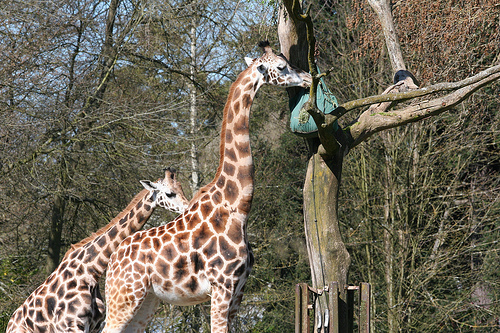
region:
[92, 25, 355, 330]
tall giraffe looking at the tree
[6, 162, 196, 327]
smaller giraffe standing behind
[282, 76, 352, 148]
blue bag in the tree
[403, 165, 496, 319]
bare branches on the tree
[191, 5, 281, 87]
blue skies behind tree branches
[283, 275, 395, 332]
wooden makeshift fence around tree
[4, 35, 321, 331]
adult giraffe and baby giraffe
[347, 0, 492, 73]
few leaves left on the tree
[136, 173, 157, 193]
white ear on giraffe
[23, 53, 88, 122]
blue skies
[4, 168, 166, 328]
Giraffe standing by trees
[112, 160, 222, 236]
Ears on a giraffe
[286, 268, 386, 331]
Wood posts around a tree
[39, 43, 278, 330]
Two giraffes by trees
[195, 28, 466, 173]
Giraffe head by a tree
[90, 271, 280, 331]
Four giraffe legs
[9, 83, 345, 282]
Trees behind giraffes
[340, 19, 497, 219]
Brown and green trees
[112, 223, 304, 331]
Orange and brown giraffe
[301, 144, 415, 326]
Green moss on a tree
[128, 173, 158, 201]
tan ears on small giraffe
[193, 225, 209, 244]
dark brown spot on large giraffe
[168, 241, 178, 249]
white spot on giraffe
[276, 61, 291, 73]
slanted eye on giraffe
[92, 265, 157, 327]
wide hind leg on giraffe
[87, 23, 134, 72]
large bare branch on tree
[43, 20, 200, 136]
lots of bare tall trees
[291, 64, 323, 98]
giraffe's mouth on tree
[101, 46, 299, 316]
large giraffe standing on ground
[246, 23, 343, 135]
A giraffe eating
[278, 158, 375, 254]
The bark of a tree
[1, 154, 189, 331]
A giraffe standing next to another giraffe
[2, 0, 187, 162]
Leafless trees behind the giraffes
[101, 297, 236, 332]
Front and back legs of the giraffe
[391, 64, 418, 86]
A black object on the tree branch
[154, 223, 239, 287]
Brown and black spots on the giraffe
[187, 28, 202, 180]
The bark of a tree in the distance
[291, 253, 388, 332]
Bottom of the tree secured in a wooden object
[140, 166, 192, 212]
A giraffes head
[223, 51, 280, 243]
the girrafe is very tall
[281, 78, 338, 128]
the sack is green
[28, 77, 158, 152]
the trees are bare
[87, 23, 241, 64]
the sky is cloudless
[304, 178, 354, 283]
the tree is dark grey in color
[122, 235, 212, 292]
the skin is colorful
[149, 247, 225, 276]
the spots are brown and white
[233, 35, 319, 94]
the giraffe is eating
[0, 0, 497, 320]
photo was taken during the day